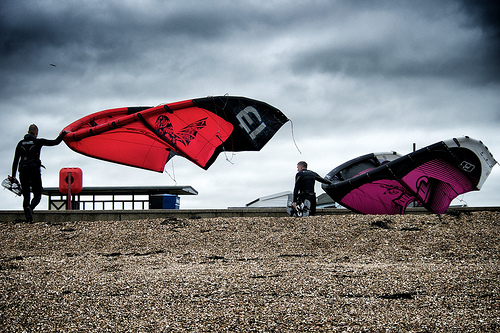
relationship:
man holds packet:
[12, 123, 71, 222] [2, 176, 24, 197]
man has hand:
[12, 123, 71, 222] [11, 173, 16, 184]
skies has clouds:
[0, 1, 500, 206] [1, 3, 499, 204]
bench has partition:
[41, 185, 200, 209] [79, 196, 149, 208]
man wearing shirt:
[12, 123, 71, 222] [16, 138, 64, 172]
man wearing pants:
[12, 123, 71, 222] [19, 172, 41, 223]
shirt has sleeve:
[16, 138, 64, 172] [43, 134, 63, 147]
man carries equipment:
[12, 123, 71, 222] [2, 176, 24, 197]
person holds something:
[12, 123, 71, 222] [60, 93, 292, 174]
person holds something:
[290, 161, 334, 220] [322, 136, 497, 216]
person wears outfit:
[290, 161, 334, 220] [296, 170, 331, 210]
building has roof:
[247, 190, 339, 208] [258, 189, 331, 199]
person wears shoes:
[12, 123, 71, 222] [20, 206, 35, 226]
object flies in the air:
[60, 93, 292, 174] [0, 1, 500, 206]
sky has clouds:
[0, 1, 500, 206] [1, 3, 499, 204]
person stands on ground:
[12, 123, 71, 222] [2, 207, 500, 332]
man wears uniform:
[12, 123, 71, 222] [11, 134, 60, 216]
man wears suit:
[12, 123, 71, 222] [11, 134, 60, 216]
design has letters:
[234, 106, 270, 151] [238, 104, 264, 137]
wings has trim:
[322, 136, 497, 216] [326, 151, 377, 188]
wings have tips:
[322, 136, 497, 216] [448, 134, 499, 168]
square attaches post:
[62, 170, 83, 196] [67, 172, 73, 210]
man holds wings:
[290, 161, 334, 220] [322, 136, 497, 216]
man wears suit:
[290, 161, 334, 220] [296, 170, 331, 210]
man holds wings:
[12, 123, 71, 222] [60, 93, 292, 174]